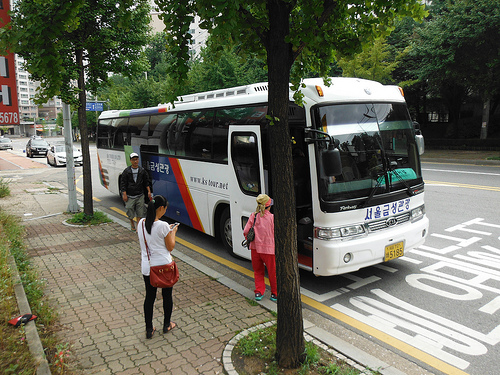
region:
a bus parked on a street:
[97, 75, 429, 279]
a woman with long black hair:
[146, 193, 169, 233]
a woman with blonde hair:
[257, 192, 272, 214]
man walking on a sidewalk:
[118, 152, 153, 234]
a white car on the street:
[46, 140, 84, 167]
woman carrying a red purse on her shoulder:
[140, 217, 178, 287]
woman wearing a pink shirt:
[242, 210, 274, 252]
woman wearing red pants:
[251, 249, 276, 297]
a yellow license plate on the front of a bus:
[386, 239, 408, 260]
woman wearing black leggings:
[143, 275, 173, 330]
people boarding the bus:
[18, 106, 432, 331]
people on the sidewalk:
[45, 162, 240, 360]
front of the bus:
[306, 100, 443, 203]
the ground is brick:
[62, 278, 128, 358]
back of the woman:
[114, 188, 188, 339]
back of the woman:
[230, 175, 288, 303]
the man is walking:
[111, 135, 150, 214]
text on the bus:
[182, 173, 235, 198]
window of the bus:
[64, 120, 231, 157]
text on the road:
[427, 250, 483, 343]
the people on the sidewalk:
[116, 149, 191, 339]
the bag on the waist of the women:
[148, 257, 183, 291]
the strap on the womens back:
[140, 217, 155, 259]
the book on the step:
[8, 304, 42, 333]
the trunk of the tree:
[270, 4, 312, 370]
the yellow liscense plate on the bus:
[379, 238, 404, 265]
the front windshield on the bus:
[310, 101, 424, 202]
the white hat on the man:
[129, 151, 139, 169]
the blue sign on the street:
[83, 97, 108, 112]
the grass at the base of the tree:
[66, 202, 106, 227]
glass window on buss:
[97, 116, 109, 146]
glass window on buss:
[111, 116, 129, 149]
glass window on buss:
[126, 115, 151, 152]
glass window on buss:
[151, 110, 176, 155]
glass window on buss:
[176, 108, 195, 159]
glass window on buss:
[191, 110, 214, 157]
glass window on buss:
[216, 108, 237, 160]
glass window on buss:
[233, 105, 260, 125]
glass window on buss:
[229, 130, 261, 195]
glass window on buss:
[312, 103, 390, 205]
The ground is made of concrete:
[41, 227, 152, 349]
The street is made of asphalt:
[438, 192, 490, 360]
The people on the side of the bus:
[98, 143, 292, 342]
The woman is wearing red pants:
[242, 245, 278, 302]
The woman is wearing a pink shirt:
[240, 208, 277, 256]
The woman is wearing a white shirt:
[136, 216, 179, 277]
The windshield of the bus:
[307, 98, 427, 213]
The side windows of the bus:
[92, 112, 252, 167]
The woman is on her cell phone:
[131, 185, 186, 260]